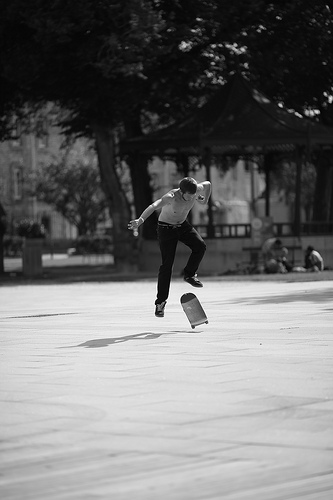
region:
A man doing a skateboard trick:
[126, 178, 212, 317]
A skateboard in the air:
[179, 291, 208, 328]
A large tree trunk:
[83, 138, 130, 237]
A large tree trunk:
[121, 114, 165, 222]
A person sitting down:
[304, 243, 325, 272]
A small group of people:
[221, 232, 324, 275]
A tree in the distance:
[28, 166, 156, 234]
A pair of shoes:
[154, 274, 202, 317]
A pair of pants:
[156, 218, 208, 302]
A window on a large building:
[11, 165, 22, 200]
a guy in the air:
[123, 168, 225, 330]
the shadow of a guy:
[55, 324, 192, 364]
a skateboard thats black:
[172, 283, 210, 329]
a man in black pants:
[131, 169, 216, 315]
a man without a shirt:
[129, 173, 240, 319]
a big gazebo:
[111, 67, 330, 269]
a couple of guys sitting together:
[253, 225, 322, 275]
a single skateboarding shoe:
[152, 299, 168, 319]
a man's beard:
[179, 191, 189, 202]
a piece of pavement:
[63, 358, 310, 473]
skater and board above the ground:
[124, 170, 212, 338]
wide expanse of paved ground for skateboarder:
[9, 280, 314, 445]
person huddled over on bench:
[246, 233, 293, 269]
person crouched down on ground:
[297, 238, 321, 269]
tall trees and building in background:
[0, 14, 319, 175]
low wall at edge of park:
[129, 228, 327, 278]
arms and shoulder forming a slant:
[120, 166, 212, 231]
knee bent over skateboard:
[173, 226, 210, 329]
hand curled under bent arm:
[191, 176, 210, 203]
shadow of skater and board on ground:
[59, 326, 204, 353]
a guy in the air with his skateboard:
[124, 161, 226, 340]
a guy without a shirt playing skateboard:
[122, 167, 225, 330]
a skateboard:
[178, 289, 212, 330]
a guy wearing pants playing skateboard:
[124, 170, 226, 336]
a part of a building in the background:
[4, 135, 69, 228]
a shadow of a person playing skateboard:
[61, 324, 178, 351]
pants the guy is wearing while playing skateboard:
[153, 218, 205, 302]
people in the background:
[239, 225, 326, 277]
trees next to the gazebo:
[17, 40, 151, 273]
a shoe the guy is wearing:
[151, 296, 170, 320]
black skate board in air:
[179, 292, 208, 329]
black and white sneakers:
[151, 275, 205, 314]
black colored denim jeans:
[156, 223, 203, 297]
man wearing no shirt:
[137, 182, 216, 308]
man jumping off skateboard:
[128, 177, 219, 322]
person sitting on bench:
[262, 236, 291, 265]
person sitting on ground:
[305, 246, 324, 272]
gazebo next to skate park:
[144, 74, 321, 231]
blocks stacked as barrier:
[147, 239, 332, 271]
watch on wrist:
[139, 217, 144, 224]